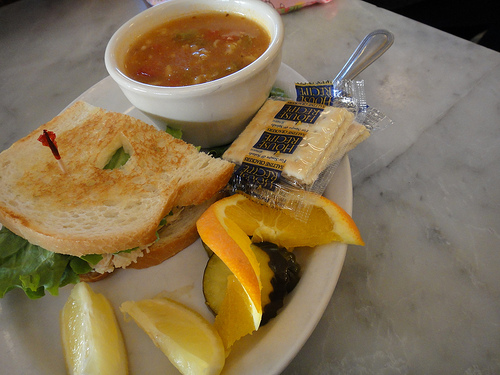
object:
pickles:
[196, 238, 302, 321]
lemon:
[60, 282, 226, 375]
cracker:
[221, 97, 372, 191]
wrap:
[205, 146, 352, 217]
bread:
[0, 99, 234, 258]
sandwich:
[0, 98, 235, 298]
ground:
[426, 160, 430, 169]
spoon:
[329, 29, 396, 94]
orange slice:
[193, 185, 365, 355]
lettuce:
[2, 225, 104, 298]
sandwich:
[2, 84, 238, 284]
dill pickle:
[248, 245, 295, 310]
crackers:
[216, 77, 396, 224]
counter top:
[2, 0, 499, 373]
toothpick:
[28, 125, 75, 174]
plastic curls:
[38, 125, 58, 152]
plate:
[28, 57, 348, 364]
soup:
[177, 22, 244, 62]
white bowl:
[173, 7, 295, 139]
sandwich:
[2, 96, 243, 278]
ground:
[313, 71, 353, 111]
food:
[3, 93, 235, 310]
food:
[59, 276, 132, 375]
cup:
[104, 1, 285, 140]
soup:
[123, 12, 270, 89]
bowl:
[103, 0, 283, 149]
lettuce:
[1, 234, 86, 301]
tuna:
[93, 245, 151, 274]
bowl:
[104, 0, 286, 108]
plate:
[2, 44, 366, 373]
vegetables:
[156, 24, 257, 83]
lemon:
[119, 288, 226, 375]